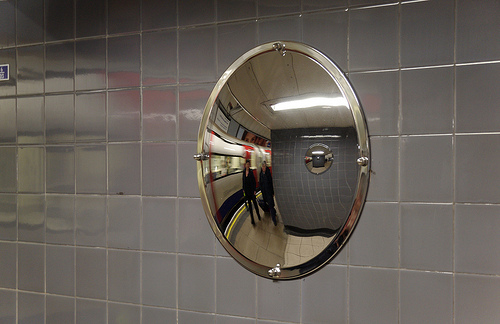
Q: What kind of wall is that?
A: Tile.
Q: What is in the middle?
A: Mirror.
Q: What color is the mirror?
A: Silver.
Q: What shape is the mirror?
A: Round.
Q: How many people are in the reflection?
A: Two.